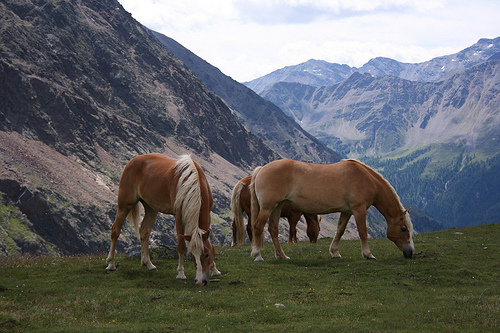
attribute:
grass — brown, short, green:
[0, 212, 500, 328]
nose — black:
[191, 270, 212, 287]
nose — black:
[394, 239, 418, 261]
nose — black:
[305, 230, 322, 247]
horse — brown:
[227, 165, 325, 242]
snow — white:
[426, 44, 496, 81]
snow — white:
[296, 64, 328, 80]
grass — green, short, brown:
[1, 268, 498, 332]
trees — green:
[359, 151, 499, 232]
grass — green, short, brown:
[16, 222, 491, 332]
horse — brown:
[251, 152, 416, 264]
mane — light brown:
[167, 152, 210, 249]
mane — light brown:
[339, 150, 421, 232]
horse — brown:
[102, 144, 224, 286]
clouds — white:
[127, 0, 499, 82]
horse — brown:
[227, 173, 252, 243]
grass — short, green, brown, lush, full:
[4, 228, 498, 330]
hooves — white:
[104, 261, 219, 279]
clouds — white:
[126, 2, 446, 29]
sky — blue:
[116, 0, 498, 86]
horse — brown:
[227, 179, 328, 243]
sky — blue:
[238, 5, 381, 21]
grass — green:
[6, 251, 496, 327]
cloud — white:
[124, 2, 498, 75]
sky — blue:
[240, 3, 410, 24]